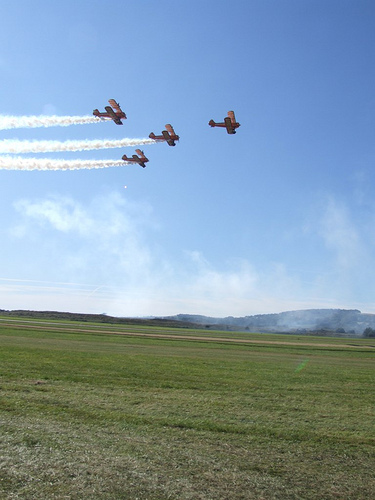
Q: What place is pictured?
A: It is a field.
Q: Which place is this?
A: It is a field.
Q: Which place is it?
A: It is a field.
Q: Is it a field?
A: Yes, it is a field.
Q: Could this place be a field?
A: Yes, it is a field.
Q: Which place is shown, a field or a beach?
A: It is a field.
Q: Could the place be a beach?
A: No, it is a field.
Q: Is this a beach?
A: No, it is a field.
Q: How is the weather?
A: It is cloudy.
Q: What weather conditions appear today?
A: It is cloudy.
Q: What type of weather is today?
A: It is cloudy.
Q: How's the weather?
A: It is cloudy.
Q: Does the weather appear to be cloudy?
A: Yes, it is cloudy.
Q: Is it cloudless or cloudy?
A: It is cloudy.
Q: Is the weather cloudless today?
A: No, it is cloudy.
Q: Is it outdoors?
A: Yes, it is outdoors.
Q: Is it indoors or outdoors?
A: It is outdoors.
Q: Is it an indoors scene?
A: No, it is outdoors.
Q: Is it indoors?
A: No, it is outdoors.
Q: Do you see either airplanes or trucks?
A: Yes, there is an airplane.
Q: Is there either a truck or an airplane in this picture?
A: Yes, there is an airplane.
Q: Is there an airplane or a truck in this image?
A: Yes, there is an airplane.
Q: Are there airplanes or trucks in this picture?
A: Yes, there is an airplane.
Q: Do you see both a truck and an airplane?
A: No, there is an airplane but no trucks.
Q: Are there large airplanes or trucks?
A: Yes, there is a large airplane.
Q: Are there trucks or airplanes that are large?
A: Yes, the airplane is large.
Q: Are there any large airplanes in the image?
A: Yes, there is a large airplane.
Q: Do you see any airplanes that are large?
A: Yes, there is an airplane that is large.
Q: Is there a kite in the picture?
A: No, there are no kites.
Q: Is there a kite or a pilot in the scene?
A: No, there are no kites or pilots.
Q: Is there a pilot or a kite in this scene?
A: No, there are no kites or pilots.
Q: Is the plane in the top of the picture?
A: Yes, the plane is in the top of the image.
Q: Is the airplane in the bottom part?
A: No, the airplane is in the top of the image.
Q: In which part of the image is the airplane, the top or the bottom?
A: The airplane is in the top of the image.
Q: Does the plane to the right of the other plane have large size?
A: Yes, the plane is large.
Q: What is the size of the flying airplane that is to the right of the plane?
A: The airplane is large.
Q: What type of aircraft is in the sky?
A: The aircraft is an airplane.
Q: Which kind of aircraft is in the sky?
A: The aircraft is an airplane.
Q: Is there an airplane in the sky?
A: Yes, there is an airplane in the sky.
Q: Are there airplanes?
A: Yes, there is an airplane.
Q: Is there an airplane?
A: Yes, there is an airplane.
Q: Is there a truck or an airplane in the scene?
A: Yes, there is an airplane.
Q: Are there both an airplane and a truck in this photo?
A: No, there is an airplane but no trucks.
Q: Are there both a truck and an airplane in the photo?
A: No, there is an airplane but no trucks.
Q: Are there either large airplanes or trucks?
A: Yes, there is a large airplane.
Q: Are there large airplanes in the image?
A: Yes, there is a large airplane.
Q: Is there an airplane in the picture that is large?
A: Yes, there is an airplane that is large.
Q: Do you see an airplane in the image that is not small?
A: Yes, there is a large airplane.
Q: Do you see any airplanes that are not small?
A: Yes, there is a large airplane.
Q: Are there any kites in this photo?
A: No, there are no kites.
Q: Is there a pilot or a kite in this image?
A: No, there are no kites or pilots.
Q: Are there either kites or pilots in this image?
A: No, there are no kites or pilots.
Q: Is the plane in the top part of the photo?
A: Yes, the plane is in the top of the image.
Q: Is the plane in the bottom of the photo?
A: No, the plane is in the top of the image.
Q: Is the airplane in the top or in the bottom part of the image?
A: The airplane is in the top of the image.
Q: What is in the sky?
A: The plane is in the sky.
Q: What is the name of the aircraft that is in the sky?
A: The aircraft is an airplane.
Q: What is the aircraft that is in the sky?
A: The aircraft is an airplane.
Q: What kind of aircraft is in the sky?
A: The aircraft is an airplane.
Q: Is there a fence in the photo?
A: No, there are no fences.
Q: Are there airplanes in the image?
A: Yes, there are airplanes.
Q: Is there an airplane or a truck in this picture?
A: Yes, there are airplanes.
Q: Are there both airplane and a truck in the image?
A: No, there are airplanes but no trucks.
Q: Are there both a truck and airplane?
A: No, there are airplanes but no trucks.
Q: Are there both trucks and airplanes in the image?
A: No, there are airplanes but no trucks.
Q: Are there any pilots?
A: No, there are no pilots.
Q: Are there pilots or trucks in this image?
A: No, there are no pilots or trucks.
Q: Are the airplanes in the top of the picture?
A: Yes, the airplanes are in the top of the image.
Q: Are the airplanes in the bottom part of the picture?
A: No, the airplanes are in the top of the image.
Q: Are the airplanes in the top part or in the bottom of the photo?
A: The airplanes are in the top of the image.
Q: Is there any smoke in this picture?
A: Yes, there is smoke.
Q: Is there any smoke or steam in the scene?
A: Yes, there is smoke.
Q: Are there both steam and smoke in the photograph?
A: No, there is smoke but no steam.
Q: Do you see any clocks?
A: No, there are no clocks.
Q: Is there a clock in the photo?
A: No, there are no clocks.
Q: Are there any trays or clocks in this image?
A: No, there are no clocks or trays.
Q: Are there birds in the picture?
A: No, there are no birds.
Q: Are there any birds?
A: No, there are no birds.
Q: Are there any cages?
A: No, there are no cages.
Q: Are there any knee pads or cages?
A: No, there are no cages or knee pads.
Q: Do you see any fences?
A: No, there are no fences.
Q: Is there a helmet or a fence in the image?
A: No, there are no fences or helmets.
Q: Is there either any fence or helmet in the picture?
A: No, there are no fences or helmets.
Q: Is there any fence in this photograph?
A: No, there are no fences.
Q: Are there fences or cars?
A: No, there are no fences or cars.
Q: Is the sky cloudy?
A: Yes, the sky is cloudy.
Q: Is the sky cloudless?
A: No, the sky is cloudy.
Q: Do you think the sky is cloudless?
A: No, the sky is cloudy.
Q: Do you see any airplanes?
A: Yes, there is an airplane.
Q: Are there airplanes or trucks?
A: Yes, there is an airplane.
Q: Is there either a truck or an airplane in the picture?
A: Yes, there is an airplane.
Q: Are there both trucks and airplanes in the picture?
A: No, there is an airplane but no trucks.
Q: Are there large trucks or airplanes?
A: Yes, there is a large airplane.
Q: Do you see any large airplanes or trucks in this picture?
A: Yes, there is a large airplane.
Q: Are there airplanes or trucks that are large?
A: Yes, the airplane is large.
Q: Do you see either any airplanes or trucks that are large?
A: Yes, the airplane is large.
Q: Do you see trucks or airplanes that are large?
A: Yes, the airplane is large.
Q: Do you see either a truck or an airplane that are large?
A: Yes, the airplane is large.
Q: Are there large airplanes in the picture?
A: Yes, there is a large airplane.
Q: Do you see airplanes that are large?
A: Yes, there is an airplane that is large.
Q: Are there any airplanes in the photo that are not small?
A: Yes, there is a large airplane.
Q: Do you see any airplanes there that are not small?
A: Yes, there is a large airplane.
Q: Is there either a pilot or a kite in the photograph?
A: No, there are no kites or pilots.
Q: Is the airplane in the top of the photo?
A: Yes, the airplane is in the top of the image.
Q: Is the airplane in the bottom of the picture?
A: No, the airplane is in the top of the image.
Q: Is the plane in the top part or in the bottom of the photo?
A: The plane is in the top of the image.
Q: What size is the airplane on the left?
A: The plane is large.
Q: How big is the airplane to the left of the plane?
A: The plane is large.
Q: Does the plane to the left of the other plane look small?
A: No, the airplane is large.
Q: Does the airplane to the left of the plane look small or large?
A: The plane is large.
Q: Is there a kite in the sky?
A: No, there is an airplane in the sky.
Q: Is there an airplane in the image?
A: Yes, there is an airplane.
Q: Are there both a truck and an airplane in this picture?
A: No, there is an airplane but no trucks.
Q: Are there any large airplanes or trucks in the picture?
A: Yes, there is a large airplane.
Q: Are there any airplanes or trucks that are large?
A: Yes, the airplane is large.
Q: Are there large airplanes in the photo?
A: Yes, there is a large airplane.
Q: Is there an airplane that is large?
A: Yes, there is an airplane that is large.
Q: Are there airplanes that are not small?
A: Yes, there is a large airplane.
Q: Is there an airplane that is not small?
A: Yes, there is a large airplane.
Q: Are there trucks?
A: No, there are no trucks.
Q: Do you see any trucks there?
A: No, there are no trucks.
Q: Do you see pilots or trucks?
A: No, there are no trucks or pilots.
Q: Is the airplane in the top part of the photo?
A: Yes, the airplane is in the top of the image.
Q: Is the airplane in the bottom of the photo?
A: No, the airplane is in the top of the image.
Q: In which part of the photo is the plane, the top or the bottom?
A: The plane is in the top of the image.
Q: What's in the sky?
A: The plane is in the sky.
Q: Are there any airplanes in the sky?
A: Yes, there is an airplane in the sky.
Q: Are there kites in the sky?
A: No, there is an airplane in the sky.